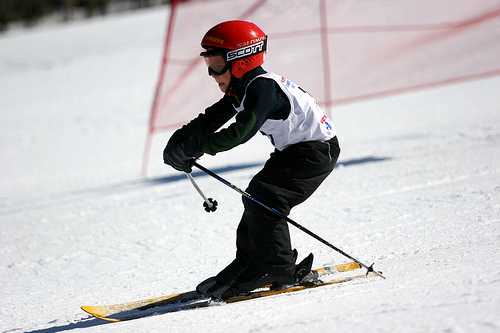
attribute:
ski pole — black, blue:
[185, 149, 391, 288]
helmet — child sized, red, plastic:
[196, 19, 273, 83]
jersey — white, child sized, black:
[223, 73, 342, 154]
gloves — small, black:
[160, 116, 208, 176]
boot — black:
[218, 254, 301, 304]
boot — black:
[188, 249, 246, 296]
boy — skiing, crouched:
[156, 11, 353, 309]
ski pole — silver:
[169, 161, 225, 221]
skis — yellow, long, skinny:
[65, 253, 382, 327]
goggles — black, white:
[193, 35, 272, 80]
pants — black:
[205, 131, 345, 295]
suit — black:
[149, 67, 348, 276]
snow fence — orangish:
[131, 1, 498, 150]